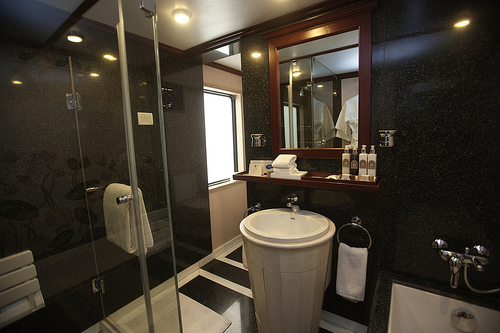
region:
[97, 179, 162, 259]
a towel on the door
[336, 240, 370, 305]
a white hand towel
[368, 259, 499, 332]
a black and white bathtub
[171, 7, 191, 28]
a light in the ceiling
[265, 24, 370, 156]
a large mirror in the bathroom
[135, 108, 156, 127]
a switch in the bathroom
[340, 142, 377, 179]
hygiene products in the bathroom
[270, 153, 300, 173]
small towels on the sink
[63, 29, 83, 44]
a light on the ceiling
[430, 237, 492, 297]
the handles for the tub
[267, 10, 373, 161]
Mirror with the glass shower door reflected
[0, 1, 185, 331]
Shower with towel hanging on the outside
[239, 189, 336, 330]
Round sink and faucet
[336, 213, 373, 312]
Hand towel hanging on a wall rack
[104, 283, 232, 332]
White mat on the floor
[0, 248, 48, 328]
White fold up shower chair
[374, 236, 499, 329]
Faucet above the bath tub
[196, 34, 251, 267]
Window through the bathroom door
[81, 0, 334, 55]
White ceiling with a bright light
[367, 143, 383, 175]
Small personal hygine bottle sitting on a shelf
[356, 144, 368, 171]
Small personal hygine bottle sitting on a shelf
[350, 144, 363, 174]
Small personal hygine bottle sitting on a shelf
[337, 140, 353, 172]
Small personal hygine bottle sitting on a shelf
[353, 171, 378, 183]
Small personal hygine bottle sitting on a shelf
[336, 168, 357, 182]
Small personal hygine bottle sitting on a shelf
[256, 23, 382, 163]
Large mirror hanging on the wall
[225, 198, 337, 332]
Large white sink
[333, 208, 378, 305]
Small silver hand towel holder on wall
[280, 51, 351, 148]
Small reflection in the mirror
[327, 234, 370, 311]
the towel in the holder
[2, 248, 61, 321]
the folding seat in the shower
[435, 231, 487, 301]
the faucet over the tub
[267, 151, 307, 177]
towels above the sink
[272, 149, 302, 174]
the white towels are folded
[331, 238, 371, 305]
the towel is white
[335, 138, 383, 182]
toiletries on the shelf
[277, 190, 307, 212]
faucet above the sink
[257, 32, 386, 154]
the mirror on the wall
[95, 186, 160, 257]
the towel on the shower door handle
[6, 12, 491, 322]
a stylish bathroom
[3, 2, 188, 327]
a glass shower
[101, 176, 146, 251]
a towel hanging on the door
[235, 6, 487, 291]
walls made of stone or granite material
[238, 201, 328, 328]
tall white sink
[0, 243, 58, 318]
fold up seat in the shower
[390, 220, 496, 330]
bathtub with a chrome faucet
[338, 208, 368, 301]
hand towel rack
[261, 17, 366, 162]
mirror above the sink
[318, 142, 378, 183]
toiletries on the counter